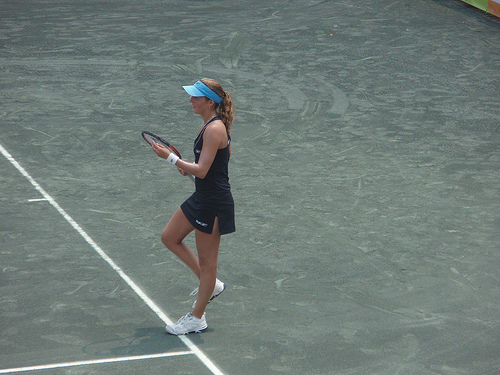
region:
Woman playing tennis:
[135, 60, 244, 345]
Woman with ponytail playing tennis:
[132, 67, 243, 349]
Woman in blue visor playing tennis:
[137, 73, 242, 339]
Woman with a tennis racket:
[132, 72, 243, 346]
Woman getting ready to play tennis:
[134, 72, 243, 344]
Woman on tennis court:
[126, 71, 241, 341]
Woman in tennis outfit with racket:
[135, 73, 245, 343]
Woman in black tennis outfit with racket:
[128, 73, 245, 340]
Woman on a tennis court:
[139, 68, 244, 342]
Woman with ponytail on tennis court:
[138, 72, 243, 340]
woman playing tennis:
[137, 74, 251, 332]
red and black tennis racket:
[134, 125, 181, 173]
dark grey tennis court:
[19, 30, 479, 350]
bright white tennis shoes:
[169, 276, 223, 335]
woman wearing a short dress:
[144, 74, 244, 344]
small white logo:
[191, 218, 210, 229]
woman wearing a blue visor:
[183, 73, 225, 122]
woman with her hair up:
[187, 76, 233, 135]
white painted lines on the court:
[2, 136, 224, 373]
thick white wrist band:
[163, 150, 177, 165]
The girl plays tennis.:
[129, 62, 246, 343]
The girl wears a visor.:
[138, 70, 245, 341]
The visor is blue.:
[178, 73, 225, 106]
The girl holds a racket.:
[140, 73, 240, 338]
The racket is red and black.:
[136, 125, 196, 183]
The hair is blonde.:
[196, 75, 233, 142]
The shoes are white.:
[163, 278, 225, 339]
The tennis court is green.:
[0, 0, 499, 374]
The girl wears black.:
[141, 75, 235, 339]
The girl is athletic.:
[136, 70, 242, 337]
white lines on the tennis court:
[0, 143, 223, 373]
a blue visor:
[179, 77, 224, 105]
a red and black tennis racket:
[138, 128, 183, 160]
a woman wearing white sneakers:
[141, 78, 236, 335]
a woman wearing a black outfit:
[157, 76, 237, 336]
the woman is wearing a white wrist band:
[141, 77, 237, 338]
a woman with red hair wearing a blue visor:
[138, 77, 235, 335]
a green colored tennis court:
[2, 0, 499, 370]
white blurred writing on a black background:
[190, 216, 210, 233]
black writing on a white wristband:
[166, 152, 178, 167]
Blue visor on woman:
[177, 82, 224, 104]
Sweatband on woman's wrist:
[166, 152, 177, 165]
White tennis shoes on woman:
[163, 277, 226, 334]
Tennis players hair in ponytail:
[200, 77, 233, 141]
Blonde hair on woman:
[199, 77, 234, 136]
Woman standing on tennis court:
[140, 77, 245, 337]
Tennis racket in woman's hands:
[139, 129, 194, 182]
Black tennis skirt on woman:
[179, 117, 239, 235]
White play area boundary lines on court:
[1, 141, 225, 374]